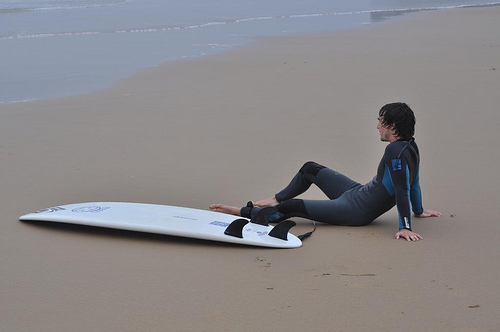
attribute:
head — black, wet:
[376, 102, 416, 141]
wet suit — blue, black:
[242, 137, 424, 226]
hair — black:
[376, 100, 416, 138]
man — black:
[207, 94, 443, 244]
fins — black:
[268, 218, 295, 239]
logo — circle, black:
[41, 184, 109, 236]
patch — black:
[298, 160, 323, 176]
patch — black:
[280, 196, 299, 213]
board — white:
[18, 199, 304, 249]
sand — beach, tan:
[0, 12, 498, 329]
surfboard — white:
[16, 197, 305, 257]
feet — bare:
[211, 181, 279, 216]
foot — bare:
[251, 195, 278, 207]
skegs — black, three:
[223, 204, 297, 241]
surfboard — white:
[19, 200, 303, 250]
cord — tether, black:
[298, 217, 318, 239]